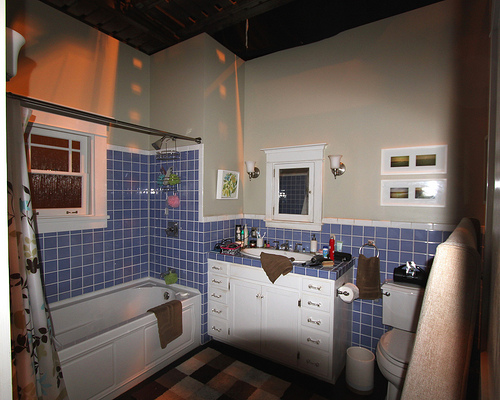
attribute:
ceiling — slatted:
[6, 1, 497, 69]